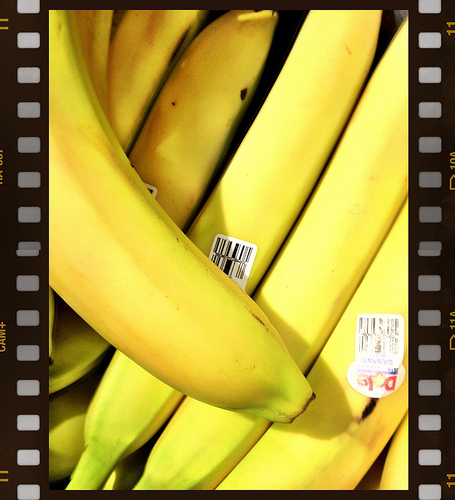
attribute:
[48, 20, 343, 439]
banana — bruised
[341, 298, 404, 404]
sticker — oblong, upside, Dole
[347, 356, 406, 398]
logo — Dole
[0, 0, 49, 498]
frame — brown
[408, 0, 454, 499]
frame — brown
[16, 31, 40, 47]
rectangle — white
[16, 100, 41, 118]
rectangle — white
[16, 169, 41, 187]
rectangle — white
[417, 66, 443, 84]
rectangle — white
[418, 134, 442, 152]
rectangle — white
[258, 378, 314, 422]
end — green, brown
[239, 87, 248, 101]
spot — small, brown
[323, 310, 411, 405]
sticker — white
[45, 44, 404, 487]
bananas — long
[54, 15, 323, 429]
banana — yellow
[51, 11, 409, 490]
bananas — Dole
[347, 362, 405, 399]
sticker — white, oval, Dole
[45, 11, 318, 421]
bananas — yellow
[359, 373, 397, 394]
lettering — red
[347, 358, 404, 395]
sticker — Dole